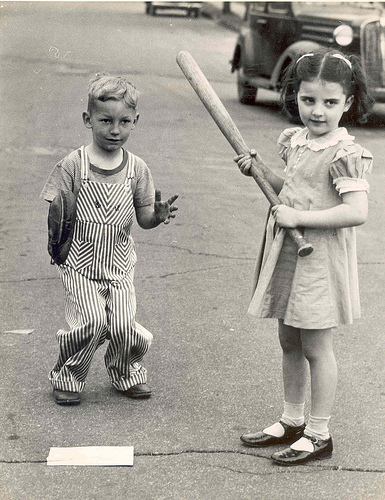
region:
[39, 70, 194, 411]
a boy is wearing striped overalls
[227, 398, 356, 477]
black shoes cover a girl's feet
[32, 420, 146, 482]
a piece of a paper laying on the pavement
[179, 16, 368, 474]
a little girl is holding a bat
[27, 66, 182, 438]
a little boy is holding a leather mitt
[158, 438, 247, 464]
a crack in the street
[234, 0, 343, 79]
an old fashioned truck in the background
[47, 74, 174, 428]
a boy crouches in the street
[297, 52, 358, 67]
barrettes are pinned in hair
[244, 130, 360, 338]
a dress has a lace collar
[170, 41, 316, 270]
a wooden baseball bat the little girl is holding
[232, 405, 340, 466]
black shiny shoes the girl is wearing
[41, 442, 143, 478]
a blank piece of paper on the ground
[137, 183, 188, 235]
the boys extended dirty hand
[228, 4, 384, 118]
a very old car in the background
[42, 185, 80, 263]
a catcher's mitt the boy is holding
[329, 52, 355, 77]
a hair clip in the girl's hair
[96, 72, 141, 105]
wavy blonde hair on the boy's head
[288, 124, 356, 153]
a white collar on the girl's dress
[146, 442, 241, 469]
a large crack in the road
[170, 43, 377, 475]
A LITTLE GIRL HOLDING A BAT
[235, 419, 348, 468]
BLACK GIRLS SHOES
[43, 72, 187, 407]
A LITTLE BOY WEARING COVERALLS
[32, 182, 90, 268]
A BASEBALL MIT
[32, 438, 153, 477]
A PIECE OF PAPER ON THE GROUND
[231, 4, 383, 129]
A CAR IN THE BACKGROUND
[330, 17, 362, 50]
A HEADLIGHT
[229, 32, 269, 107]
A REAR CAR TIRE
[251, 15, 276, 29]
A CAR DOOR HANDLE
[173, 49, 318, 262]
A WOODEN BASEBALL BAT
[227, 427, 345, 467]
the shoes are black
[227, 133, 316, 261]
the baseball is made of wood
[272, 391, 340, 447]
the socks are white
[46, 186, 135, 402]
the clothes are striped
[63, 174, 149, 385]
the clothes are black and white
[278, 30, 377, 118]
the girl has black hair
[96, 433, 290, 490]
the road has a crack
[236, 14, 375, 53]
the car is black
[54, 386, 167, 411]
the shoes are black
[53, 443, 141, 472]
the paper is white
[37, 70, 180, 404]
a small boy wears striped dungarees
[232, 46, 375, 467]
a small girl has pigtails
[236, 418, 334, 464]
shiny black mary jane shoes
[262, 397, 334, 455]
white ankle socks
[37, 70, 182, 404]
little boy has knees bent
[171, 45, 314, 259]
girl holding a wooden baseball bat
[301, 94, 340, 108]
little girl has dark eyes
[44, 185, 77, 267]
boy is wearing an old fashioned baseball glove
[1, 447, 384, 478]
crack in the pavement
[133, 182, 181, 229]
boy has a dirty hand